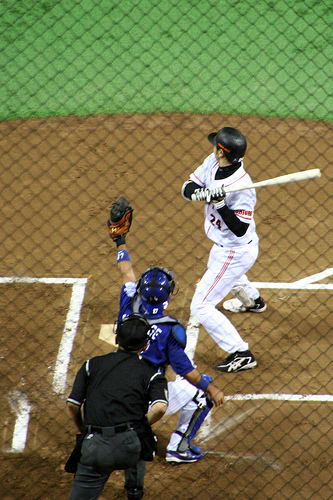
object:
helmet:
[207, 126, 247, 163]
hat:
[116, 312, 151, 351]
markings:
[0, 264, 333, 456]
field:
[0, 0, 333, 128]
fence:
[0, 3, 332, 496]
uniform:
[116, 281, 213, 465]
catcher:
[107, 196, 134, 248]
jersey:
[117, 281, 194, 377]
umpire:
[65, 312, 170, 499]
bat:
[191, 168, 322, 203]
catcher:
[107, 195, 226, 463]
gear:
[135, 265, 180, 315]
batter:
[181, 126, 267, 374]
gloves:
[211, 184, 226, 210]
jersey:
[189, 152, 259, 248]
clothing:
[67, 351, 168, 500]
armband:
[116, 249, 132, 264]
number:
[209, 213, 222, 231]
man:
[181, 126, 267, 373]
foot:
[212, 350, 257, 374]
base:
[98, 324, 119, 348]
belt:
[83, 424, 134, 436]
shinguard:
[166, 394, 214, 452]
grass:
[0, 3, 332, 120]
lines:
[0, 265, 333, 457]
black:
[65, 313, 170, 500]